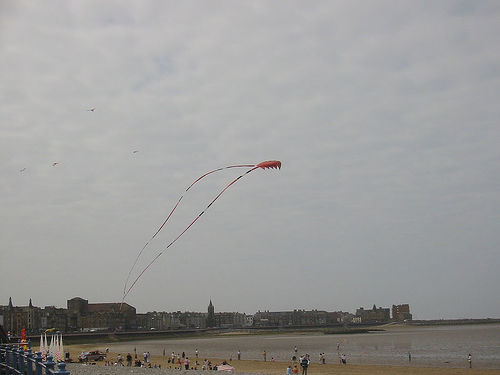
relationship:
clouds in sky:
[0, 0, 500, 319] [8, 62, 430, 273]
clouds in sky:
[0, 0, 500, 319] [0, 9, 482, 291]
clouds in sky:
[0, 0, 500, 319] [3, 17, 445, 293]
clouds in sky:
[0, 0, 500, 319] [0, 30, 463, 286]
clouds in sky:
[49, 21, 446, 121] [8, 17, 492, 303]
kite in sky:
[197, 155, 288, 188] [74, 43, 444, 273]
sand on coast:
[339, 366, 349, 373] [15, 289, 436, 373]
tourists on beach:
[101, 348, 261, 373] [210, 351, 380, 373]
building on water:
[49, 293, 142, 337] [264, 333, 458, 350]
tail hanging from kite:
[117, 153, 253, 319] [253, 153, 284, 185]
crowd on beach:
[121, 342, 224, 373] [81, 336, 468, 373]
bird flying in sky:
[132, 149, 140, 154] [8, 17, 492, 303]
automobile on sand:
[81, 343, 106, 365] [96, 352, 420, 373]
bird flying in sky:
[81, 104, 96, 117] [39, 49, 422, 282]